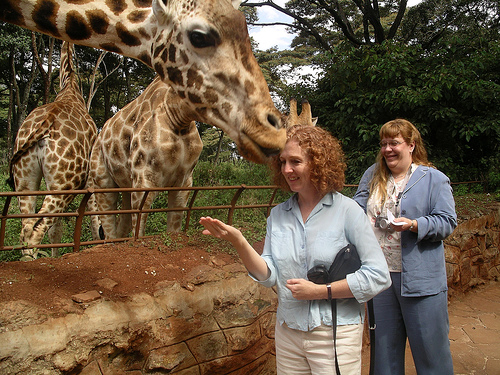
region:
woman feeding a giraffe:
[197, 107, 479, 329]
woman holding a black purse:
[299, 227, 369, 313]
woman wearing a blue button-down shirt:
[268, 206, 378, 315]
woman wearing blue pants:
[376, 268, 457, 373]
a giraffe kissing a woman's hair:
[159, 4, 310, 159]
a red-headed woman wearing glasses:
[373, 118, 418, 169]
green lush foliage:
[326, 35, 498, 110]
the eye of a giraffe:
[181, 23, 226, 61]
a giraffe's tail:
[6, 131, 45, 193]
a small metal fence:
[0, 185, 196, 240]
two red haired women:
[247, 102, 459, 302]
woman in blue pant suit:
[352, 113, 485, 373]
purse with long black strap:
[328, 239, 385, 374]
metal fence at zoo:
[0, 180, 260, 252]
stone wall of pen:
[56, 317, 259, 369]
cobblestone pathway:
[453, 301, 496, 360]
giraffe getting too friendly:
[151, 3, 297, 164]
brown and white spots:
[72, 1, 163, 51]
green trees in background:
[302, 11, 477, 110]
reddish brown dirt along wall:
[40, 239, 195, 291]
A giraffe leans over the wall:
[16, 2, 296, 190]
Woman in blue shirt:
[221, 127, 383, 359]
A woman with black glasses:
[351, 106, 473, 361]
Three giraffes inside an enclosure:
[8, 6, 258, 223]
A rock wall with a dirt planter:
[22, 189, 492, 364]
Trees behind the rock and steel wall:
[244, 7, 481, 179]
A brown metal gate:
[24, 170, 309, 254]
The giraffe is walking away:
[21, 27, 119, 232]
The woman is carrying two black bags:
[219, 124, 384, 359]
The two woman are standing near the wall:
[238, 109, 456, 357]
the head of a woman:
[266, 122, 343, 198]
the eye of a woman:
[289, 153, 302, 167]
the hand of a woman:
[195, 207, 242, 256]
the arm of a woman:
[322, 203, 394, 300]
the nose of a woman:
[281, 159, 293, 174]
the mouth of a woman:
[285, 173, 301, 183]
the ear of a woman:
[407, 135, 417, 154]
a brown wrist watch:
[323, 275, 337, 304]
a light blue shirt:
[245, 190, 393, 334]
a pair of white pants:
[271, 316, 370, 373]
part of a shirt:
[310, 215, 334, 232]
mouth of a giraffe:
[252, 127, 273, 177]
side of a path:
[190, 320, 245, 350]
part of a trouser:
[299, 338, 334, 368]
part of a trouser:
[396, 300, 416, 337]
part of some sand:
[109, 269, 136, 291]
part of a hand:
[196, 195, 226, 241]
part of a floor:
[465, 307, 491, 352]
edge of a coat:
[398, 263, 413, 295]